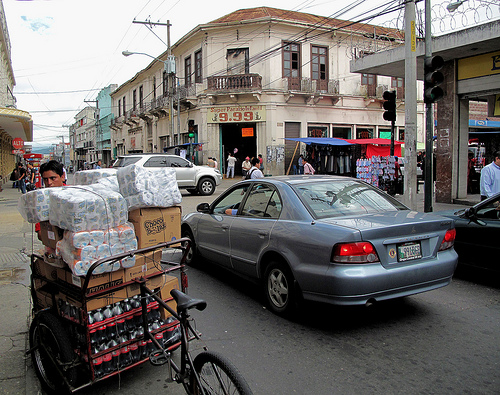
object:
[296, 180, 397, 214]
reflection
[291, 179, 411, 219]
back window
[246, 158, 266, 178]
man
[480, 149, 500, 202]
man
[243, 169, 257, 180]
backpack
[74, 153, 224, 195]
suv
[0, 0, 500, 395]
city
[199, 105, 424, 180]
store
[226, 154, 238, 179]
man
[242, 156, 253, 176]
man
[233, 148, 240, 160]
man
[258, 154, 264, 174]
man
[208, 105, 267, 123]
sign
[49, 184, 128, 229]
goods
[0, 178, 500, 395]
road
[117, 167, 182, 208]
paper towels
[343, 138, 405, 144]
red roof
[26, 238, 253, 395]
bike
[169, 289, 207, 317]
seat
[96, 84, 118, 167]
building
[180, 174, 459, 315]
car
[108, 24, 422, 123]
story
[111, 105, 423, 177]
story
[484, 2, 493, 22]
barbwire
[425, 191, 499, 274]
black car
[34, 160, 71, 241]
man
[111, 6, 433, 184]
building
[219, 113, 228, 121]
red numbers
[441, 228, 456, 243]
light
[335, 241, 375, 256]
light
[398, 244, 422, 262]
license plate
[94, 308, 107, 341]
bottle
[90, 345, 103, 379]
bottle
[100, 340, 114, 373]
bottle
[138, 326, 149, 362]
bottle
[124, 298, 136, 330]
bottle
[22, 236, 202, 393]
cart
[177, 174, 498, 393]
city street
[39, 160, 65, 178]
hair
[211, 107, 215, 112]
letters